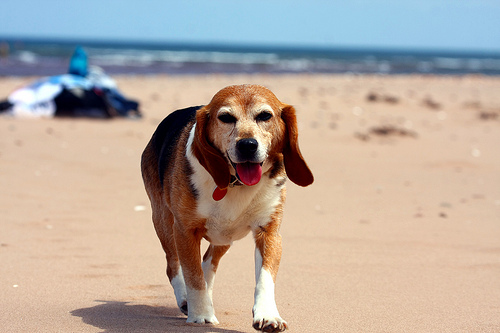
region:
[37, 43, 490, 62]
water behind the dog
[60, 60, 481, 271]
sand on the beach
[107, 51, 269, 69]
waves in the water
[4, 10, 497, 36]
the blue sky behind the water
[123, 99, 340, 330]
a dog walking on the beach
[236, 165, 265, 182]
the tongue of the dog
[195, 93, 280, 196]
a dog wearing a name tag on its collar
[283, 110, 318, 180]
the ear of the dog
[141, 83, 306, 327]
a beagle walks toward the camera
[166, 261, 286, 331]
white on the all four paws and lower legs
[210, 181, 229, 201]
a red tag hangs from the neck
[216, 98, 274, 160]
white over the eyes and on the muzzle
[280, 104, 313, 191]
floppy ears blow to the left of the beagle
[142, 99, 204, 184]
black fur on the back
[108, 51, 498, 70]
white capped waves rolling into the shore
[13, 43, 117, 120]
something blurry on the beach is blue and white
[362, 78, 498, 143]
rocks scattered on the sand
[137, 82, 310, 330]
Brown and white dog.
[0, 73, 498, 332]
The dog is walking on a sandy beach.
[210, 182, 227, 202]
A red tag hanging from the collar.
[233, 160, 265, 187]
The dogs tongue is hanging out.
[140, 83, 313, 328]
White fur on the dog's chest and legs.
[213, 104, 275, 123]
White patches of fur above the eyes.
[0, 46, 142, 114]
A pile of clothing lying on the sand.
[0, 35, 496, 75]
Ocean water with a wave rolling towards the beach.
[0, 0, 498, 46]
Bright blue sky above the water.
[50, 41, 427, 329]
A dog is walking on the beach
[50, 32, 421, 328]
A dog is walking with his tongue out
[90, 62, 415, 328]
The dog is walking in the sand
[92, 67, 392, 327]
The dog is looking for his master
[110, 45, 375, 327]
The dog is looking for food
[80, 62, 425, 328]
The dog has big floppy ears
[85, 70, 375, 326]
The dog is out in the daytime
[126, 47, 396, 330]
The dog is enjoying the day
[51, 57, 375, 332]
The dog is casting a shadow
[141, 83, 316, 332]
a beagle walking on a beach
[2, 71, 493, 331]
a tan colored sandy beach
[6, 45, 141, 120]
people sitting on the beach behind the dog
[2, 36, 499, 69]
blue ocean water on the horizon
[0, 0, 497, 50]
a blue sky above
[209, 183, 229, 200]
a red dog tag around the dog's neck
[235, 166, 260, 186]
dog's red tongue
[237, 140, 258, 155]
dog's black nose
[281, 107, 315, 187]
dog's left ear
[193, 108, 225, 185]
the dog's right ear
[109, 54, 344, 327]
dog on a beach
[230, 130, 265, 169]
Dog has a dark snout on its mouth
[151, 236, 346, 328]
Beagle has white paws and is walking on the beach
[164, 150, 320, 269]
Collar around the dog with the large ears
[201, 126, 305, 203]
Beagle has his mouth open as it walks in the sand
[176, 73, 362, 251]
Dog is staring directly at the camera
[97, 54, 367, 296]
Dog panting on the sand because it is hot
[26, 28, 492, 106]
Frothy waves behind the panting dog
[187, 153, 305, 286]
The white chest on the dog on the sand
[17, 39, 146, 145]
An object out of focus behind the big eared dog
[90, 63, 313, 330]
dog is on the beach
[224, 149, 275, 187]
dog has tongue hanging out of mouth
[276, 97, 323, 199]
dog has floppy ears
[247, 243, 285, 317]
dog has white fur by feet